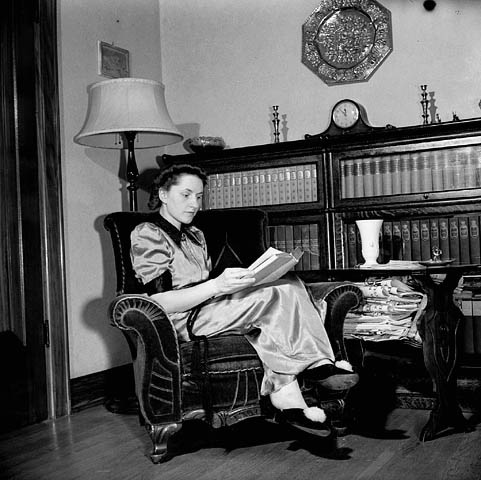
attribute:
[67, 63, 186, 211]
lamp — here, huge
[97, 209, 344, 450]
chair — large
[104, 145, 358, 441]
woman — sitting, reading, here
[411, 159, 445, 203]
book — read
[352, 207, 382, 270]
vase — white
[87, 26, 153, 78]
picture — framed, here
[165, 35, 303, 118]
wall — white, here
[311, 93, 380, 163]
clock — here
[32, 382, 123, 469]
floor — wooden, woode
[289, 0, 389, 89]
plate — copper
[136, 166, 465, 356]
bookshelf — here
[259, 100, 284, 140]
cadlestick — brass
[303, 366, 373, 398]
slippers — velvet